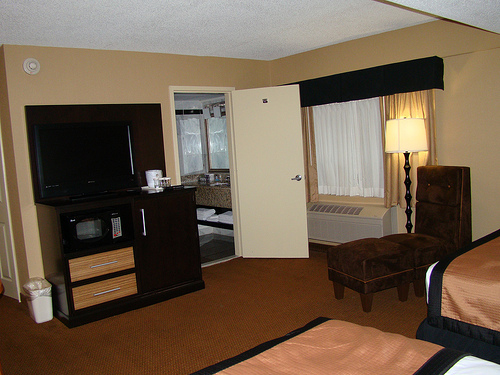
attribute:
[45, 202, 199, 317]
cabinet — black, wooden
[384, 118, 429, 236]
lamp — lit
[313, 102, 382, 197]
curtain — drawn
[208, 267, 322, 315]
carpet — brown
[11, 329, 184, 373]
floor — brown, carpeted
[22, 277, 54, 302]
bag — white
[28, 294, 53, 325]
trash-can — white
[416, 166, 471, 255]
chair — brown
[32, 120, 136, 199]
tv — black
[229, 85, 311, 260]
door — white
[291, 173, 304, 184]
handle — silver